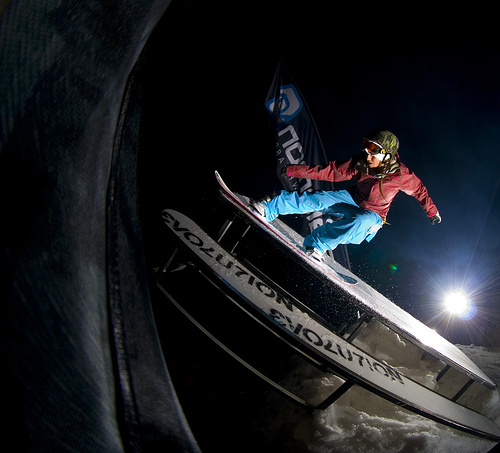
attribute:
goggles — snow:
[357, 140, 396, 158]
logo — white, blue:
[266, 84, 303, 125]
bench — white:
[156, 205, 498, 440]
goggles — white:
[352, 138, 383, 158]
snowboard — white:
[228, 177, 495, 390]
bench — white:
[152, 167, 498, 447]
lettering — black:
[162, 210, 404, 387]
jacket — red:
[284, 153, 439, 222]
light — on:
[433, 277, 485, 329]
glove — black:
[273, 156, 290, 178]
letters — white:
[278, 123, 338, 241]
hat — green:
[357, 122, 406, 160]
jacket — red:
[290, 122, 454, 229]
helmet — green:
[353, 125, 405, 164]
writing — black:
[163, 210, 405, 386]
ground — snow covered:
[331, 328, 442, 450]